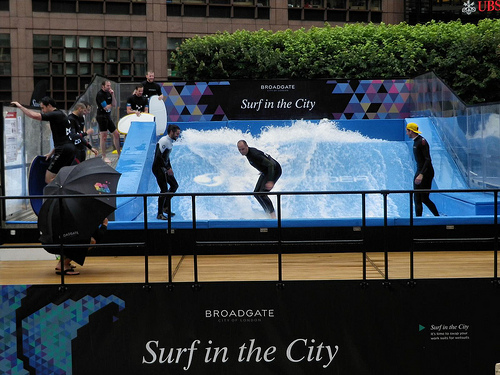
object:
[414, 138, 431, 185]
arm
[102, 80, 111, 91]
head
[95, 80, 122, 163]
person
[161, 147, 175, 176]
arm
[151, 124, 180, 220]
person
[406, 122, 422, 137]
head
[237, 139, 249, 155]
head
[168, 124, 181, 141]
head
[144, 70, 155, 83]
head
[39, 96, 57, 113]
head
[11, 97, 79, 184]
person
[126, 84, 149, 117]
person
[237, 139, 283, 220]
person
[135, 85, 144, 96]
head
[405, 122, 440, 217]
person